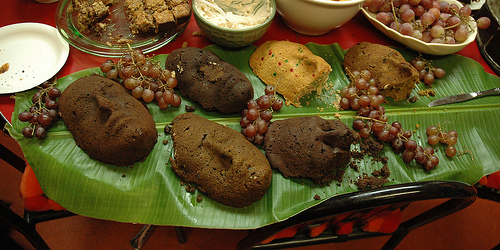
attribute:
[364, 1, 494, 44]
grapes — red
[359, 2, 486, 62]
bowl — white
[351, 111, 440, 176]
grapes — red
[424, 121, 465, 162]
grapes — red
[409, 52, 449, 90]
grapes — red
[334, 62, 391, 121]
grapes — red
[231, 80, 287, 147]
grapes — red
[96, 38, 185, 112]
grapes — red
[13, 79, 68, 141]
grapes — red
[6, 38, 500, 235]
leaf — green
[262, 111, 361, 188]
cookies — chocolate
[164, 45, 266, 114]
cookies — chocolate, face, faces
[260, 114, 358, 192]
cookies — face, faces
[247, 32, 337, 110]
cookies — sprinkled, face, faces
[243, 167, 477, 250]
chair — black, metal, wooden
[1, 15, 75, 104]
plate — empty, white, paper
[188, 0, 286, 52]
bowl — green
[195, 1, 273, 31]
frosting — white, creamy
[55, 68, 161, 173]
cookies — face, faces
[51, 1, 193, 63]
dish — glass, clear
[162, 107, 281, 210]
cookies — face, faces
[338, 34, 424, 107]
cookies — face, faces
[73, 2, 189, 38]
brownies — chocolate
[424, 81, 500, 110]
knife — available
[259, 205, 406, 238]
cushion — red